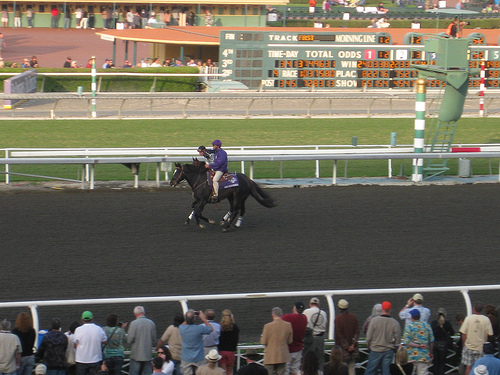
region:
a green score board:
[200, 17, 496, 111]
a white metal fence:
[21, 281, 492, 350]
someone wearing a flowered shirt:
[398, 307, 459, 366]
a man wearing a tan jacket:
[243, 298, 289, 370]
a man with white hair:
[116, 296, 171, 373]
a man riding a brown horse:
[158, 125, 325, 274]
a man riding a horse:
[166, 118, 286, 242]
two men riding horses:
[156, 118, 302, 251]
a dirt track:
[161, 190, 483, 302]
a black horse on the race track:
[168, 160, 281, 235]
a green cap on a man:
[80, 309, 94, 322]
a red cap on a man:
[380, 301, 392, 311]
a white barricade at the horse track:
[0, 278, 498, 359]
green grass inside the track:
[0, 115, 496, 182]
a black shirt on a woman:
[217, 323, 242, 348]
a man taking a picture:
[178, 308, 212, 373]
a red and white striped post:
[475, 56, 487, 118]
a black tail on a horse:
[249, 181, 277, 213]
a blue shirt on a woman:
[210, 147, 227, 172]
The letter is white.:
[263, 31, 275, 43]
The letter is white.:
[271, 31, 281, 45]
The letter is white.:
[276, 31, 287, 47]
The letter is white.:
[283, 32, 294, 46]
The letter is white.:
[301, 45, 312, 61]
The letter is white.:
[309, 49, 320, 60]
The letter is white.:
[315, 46, 325, 62]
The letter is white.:
[327, 48, 335, 60]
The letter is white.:
[353, 47, 365, 63]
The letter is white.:
[334, 77, 343, 89]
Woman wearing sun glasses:
[157, 345, 173, 373]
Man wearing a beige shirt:
[195, 347, 228, 374]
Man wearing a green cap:
[73, 312, 104, 374]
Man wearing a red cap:
[367, 300, 398, 373]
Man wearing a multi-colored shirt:
[405, 306, 433, 373]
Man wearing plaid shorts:
[458, 303, 493, 374]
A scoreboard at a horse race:
[219, 31, 499, 88]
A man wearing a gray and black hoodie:
[35, 315, 70, 373]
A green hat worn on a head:
[80, 308, 92, 320]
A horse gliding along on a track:
[170, 139, 277, 229]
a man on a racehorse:
[167, 137, 275, 233]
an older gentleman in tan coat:
[257, 303, 294, 373]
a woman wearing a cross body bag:
[97, 313, 129, 374]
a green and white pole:
[410, 77, 428, 184]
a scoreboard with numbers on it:
[217, 28, 499, 89]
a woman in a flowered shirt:
[400, 308, 436, 373]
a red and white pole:
[477, 54, 486, 117]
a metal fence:
[0, 142, 497, 189]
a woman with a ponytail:
[215, 305, 240, 373]